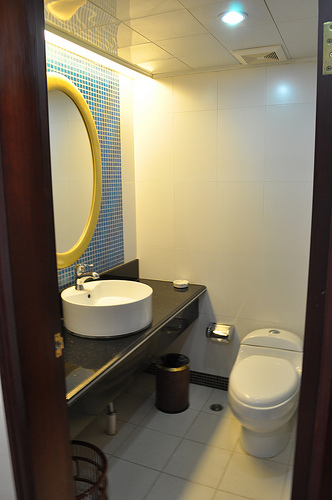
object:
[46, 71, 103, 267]
mirror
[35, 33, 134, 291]
wall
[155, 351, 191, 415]
trash can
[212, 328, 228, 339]
toilet paper roll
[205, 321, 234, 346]
dispenser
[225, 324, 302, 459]
toilet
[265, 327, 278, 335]
button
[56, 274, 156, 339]
sink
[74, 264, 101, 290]
faucet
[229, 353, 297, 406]
toilet seat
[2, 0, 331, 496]
room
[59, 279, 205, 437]
counter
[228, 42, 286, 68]
vent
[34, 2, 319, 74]
ceiling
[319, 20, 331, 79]
hinge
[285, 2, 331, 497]
door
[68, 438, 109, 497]
basket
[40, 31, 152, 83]
lighting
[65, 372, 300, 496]
floor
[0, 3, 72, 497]
door trim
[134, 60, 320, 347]
wall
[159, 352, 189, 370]
lid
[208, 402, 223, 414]
drain